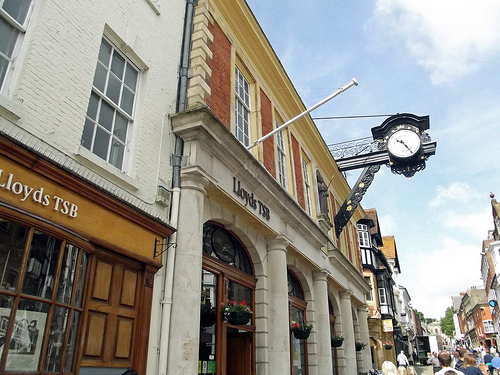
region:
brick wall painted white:
[40, 6, 84, 123]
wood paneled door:
[76, 236, 144, 374]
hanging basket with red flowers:
[223, 265, 263, 342]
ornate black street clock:
[325, 109, 436, 241]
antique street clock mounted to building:
[308, 105, 440, 238]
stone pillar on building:
[180, 163, 213, 374]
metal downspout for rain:
[175, 1, 196, 108]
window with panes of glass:
[82, 7, 156, 186]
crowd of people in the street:
[373, 338, 498, 374]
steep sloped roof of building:
[379, 231, 406, 273]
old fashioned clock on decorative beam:
[314, 111, 439, 237]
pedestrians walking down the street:
[368, 332, 498, 374]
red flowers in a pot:
[223, 297, 255, 326]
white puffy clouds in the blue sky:
[246, 0, 499, 320]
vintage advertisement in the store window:
[0, 215, 89, 372]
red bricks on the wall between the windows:
[191, 1, 364, 269]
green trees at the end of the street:
[410, 303, 458, 373]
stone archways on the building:
[147, 0, 373, 372]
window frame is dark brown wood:
[2, 199, 99, 374]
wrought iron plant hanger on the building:
[0, 0, 197, 373]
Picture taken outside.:
[283, 6, 446, 216]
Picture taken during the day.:
[301, 49, 422, 359]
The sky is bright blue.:
[296, 6, 412, 91]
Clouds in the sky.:
[379, 9, 471, 86]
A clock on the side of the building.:
[319, 104, 475, 202]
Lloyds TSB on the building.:
[6, 151, 106, 266]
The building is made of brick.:
[37, 42, 249, 131]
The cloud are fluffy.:
[369, 14, 482, 129]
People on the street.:
[366, 269, 498, 345]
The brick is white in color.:
[33, 4, 79, 142]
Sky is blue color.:
[284, 18, 377, 96]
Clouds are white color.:
[416, 3, 498, 70]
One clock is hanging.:
[375, 106, 435, 180]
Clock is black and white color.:
[344, 113, 426, 193]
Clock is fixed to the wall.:
[326, 126, 441, 251]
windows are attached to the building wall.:
[13, 57, 400, 252]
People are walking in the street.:
[415, 341, 492, 374]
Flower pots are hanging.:
[220, 288, 408, 368]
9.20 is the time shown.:
[381, 128, 441, 173]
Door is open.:
[222, 328, 252, 374]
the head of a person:
[438, 349, 453, 365]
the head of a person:
[380, 358, 397, 373]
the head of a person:
[394, 363, 407, 373]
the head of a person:
[405, 360, 417, 373]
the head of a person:
[461, 350, 478, 366]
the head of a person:
[456, 345, 473, 358]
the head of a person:
[476, 360, 489, 370]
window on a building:
[233, 57, 253, 145]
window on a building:
[274, 114, 286, 183]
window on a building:
[299, 150, 314, 210]